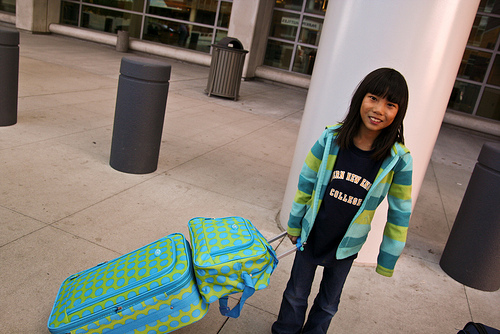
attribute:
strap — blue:
[219, 291, 263, 323]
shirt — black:
[306, 136, 382, 250]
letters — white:
[330, 168, 371, 209]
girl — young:
[301, 48, 453, 332]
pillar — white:
[274, 1, 481, 267]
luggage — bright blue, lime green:
[38, 213, 291, 332]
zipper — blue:
[69, 278, 191, 332]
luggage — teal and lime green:
[42, 208, 311, 332]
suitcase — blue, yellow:
[35, 233, 204, 331]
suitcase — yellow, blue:
[176, 200, 295, 317]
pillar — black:
[80, 47, 203, 207]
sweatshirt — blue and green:
[286, 117, 414, 276]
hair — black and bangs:
[337, 67, 406, 153]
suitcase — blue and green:
[46, 225, 287, 324]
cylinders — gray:
[108, 57, 165, 175]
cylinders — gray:
[437, 139, 499, 294]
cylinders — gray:
[1, 28, 21, 126]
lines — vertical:
[212, 51, 241, 96]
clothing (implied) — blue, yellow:
[286, 124, 413, 277]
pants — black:
[266, 263, 330, 334]